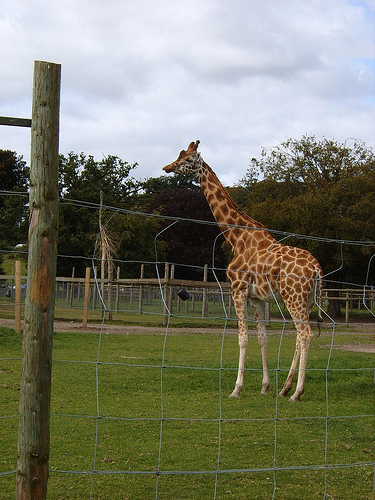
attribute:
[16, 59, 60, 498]
post — wood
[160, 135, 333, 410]
giraffe — standing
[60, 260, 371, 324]
fencing — behind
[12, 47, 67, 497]
post — wood, natural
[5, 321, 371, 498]
grassland — short trimmed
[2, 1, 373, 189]
clouds — puffy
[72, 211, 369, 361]
structure — large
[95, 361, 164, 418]
gaps — square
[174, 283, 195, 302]
bucket — hanging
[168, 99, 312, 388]
giraffe — tall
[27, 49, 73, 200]
trunks — small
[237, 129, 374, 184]
tree — tall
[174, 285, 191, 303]
barrel — black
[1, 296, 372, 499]
grass — green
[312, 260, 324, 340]
tail — short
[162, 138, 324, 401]
giraffe — back, large, full grown, standing